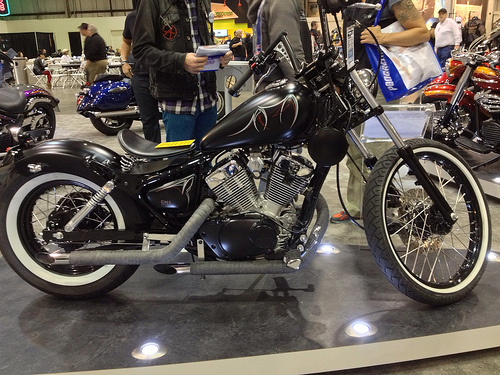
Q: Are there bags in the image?
A: Yes, there is a bag.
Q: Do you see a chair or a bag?
A: Yes, there is a bag.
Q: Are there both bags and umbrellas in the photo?
A: No, there is a bag but no umbrellas.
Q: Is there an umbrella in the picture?
A: No, there are no umbrellas.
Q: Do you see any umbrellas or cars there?
A: No, there are no umbrellas or cars.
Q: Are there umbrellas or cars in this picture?
A: No, there are no umbrellas or cars.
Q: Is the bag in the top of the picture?
A: Yes, the bag is in the top of the image.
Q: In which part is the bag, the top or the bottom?
A: The bag is in the top of the image.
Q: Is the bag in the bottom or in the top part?
A: The bag is in the top of the image.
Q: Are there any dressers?
A: No, there are no dressers.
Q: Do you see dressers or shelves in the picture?
A: No, there are no dressers or shelves.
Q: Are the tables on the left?
A: Yes, the tables are on the left of the image.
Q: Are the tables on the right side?
A: No, the tables are on the left of the image.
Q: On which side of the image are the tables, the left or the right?
A: The tables are on the left of the image.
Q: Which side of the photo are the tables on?
A: The tables are on the left of the image.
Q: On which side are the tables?
A: The tables are on the left of the image.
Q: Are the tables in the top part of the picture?
A: Yes, the tables are in the top of the image.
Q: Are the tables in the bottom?
A: No, the tables are in the top of the image.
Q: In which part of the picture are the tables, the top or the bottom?
A: The tables are in the top of the image.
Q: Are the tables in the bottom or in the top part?
A: The tables are in the top of the image.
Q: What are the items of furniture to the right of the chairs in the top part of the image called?
A: The pieces of furniture are tables.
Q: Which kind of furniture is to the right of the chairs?
A: The pieces of furniture are tables.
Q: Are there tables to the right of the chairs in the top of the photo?
A: Yes, there are tables to the right of the chairs.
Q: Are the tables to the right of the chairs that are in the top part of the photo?
A: Yes, the tables are to the right of the chairs.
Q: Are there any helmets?
A: No, there are no helmets.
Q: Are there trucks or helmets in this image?
A: No, there are no helmets or trucks.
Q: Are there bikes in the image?
A: Yes, there is a bike.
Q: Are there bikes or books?
A: Yes, there is a bike.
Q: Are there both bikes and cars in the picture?
A: No, there is a bike but no cars.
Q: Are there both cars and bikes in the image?
A: No, there is a bike but no cars.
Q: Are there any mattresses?
A: No, there are no mattresses.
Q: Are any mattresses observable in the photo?
A: No, there are no mattresses.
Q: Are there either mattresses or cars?
A: No, there are no mattresses or cars.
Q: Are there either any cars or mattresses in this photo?
A: No, there are no mattresses or cars.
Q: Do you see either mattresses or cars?
A: No, there are no mattresses or cars.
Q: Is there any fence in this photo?
A: No, there are no fences.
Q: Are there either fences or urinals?
A: No, there are no fences or urinals.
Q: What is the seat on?
A: The seat is on the bike.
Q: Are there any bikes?
A: Yes, there is a bike.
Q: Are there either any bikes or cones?
A: Yes, there is a bike.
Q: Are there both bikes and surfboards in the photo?
A: No, there is a bike but no surfboards.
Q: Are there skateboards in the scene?
A: No, there are no skateboards.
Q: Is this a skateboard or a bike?
A: This is a bike.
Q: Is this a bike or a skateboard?
A: This is a bike.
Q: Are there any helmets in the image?
A: No, there are no helmets.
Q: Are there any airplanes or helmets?
A: No, there are no helmets or airplanes.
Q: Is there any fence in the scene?
A: No, there are no fences.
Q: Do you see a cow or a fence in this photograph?
A: No, there are no fences or cows.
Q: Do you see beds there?
A: No, there are no beds.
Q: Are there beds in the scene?
A: No, there are no beds.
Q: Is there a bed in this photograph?
A: No, there are no beds.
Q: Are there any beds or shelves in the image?
A: No, there are no beds or shelves.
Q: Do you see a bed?
A: No, there are no beds.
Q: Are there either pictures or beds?
A: No, there are no beds or pictures.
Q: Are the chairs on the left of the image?
A: Yes, the chairs are on the left of the image.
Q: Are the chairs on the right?
A: No, the chairs are on the left of the image.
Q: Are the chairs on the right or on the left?
A: The chairs are on the left of the image.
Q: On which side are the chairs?
A: The chairs are on the left of the image.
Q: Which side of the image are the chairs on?
A: The chairs are on the left of the image.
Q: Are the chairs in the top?
A: Yes, the chairs are in the top of the image.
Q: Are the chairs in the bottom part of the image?
A: No, the chairs are in the top of the image.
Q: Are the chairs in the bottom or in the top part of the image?
A: The chairs are in the top of the image.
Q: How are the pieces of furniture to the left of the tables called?
A: The pieces of furniture are chairs.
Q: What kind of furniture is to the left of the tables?
A: The pieces of furniture are chairs.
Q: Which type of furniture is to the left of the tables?
A: The pieces of furniture are chairs.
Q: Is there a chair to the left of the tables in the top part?
A: Yes, there are chairs to the left of the tables.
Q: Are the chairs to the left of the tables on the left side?
A: Yes, the chairs are to the left of the tables.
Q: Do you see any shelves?
A: No, there are no shelves.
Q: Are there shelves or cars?
A: No, there are no shelves or cars.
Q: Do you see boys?
A: No, there are no boys.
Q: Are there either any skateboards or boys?
A: No, there are no boys or skateboards.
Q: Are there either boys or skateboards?
A: No, there are no boys or skateboards.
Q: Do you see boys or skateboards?
A: No, there are no boys or skateboards.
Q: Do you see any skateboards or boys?
A: No, there are no boys or skateboards.